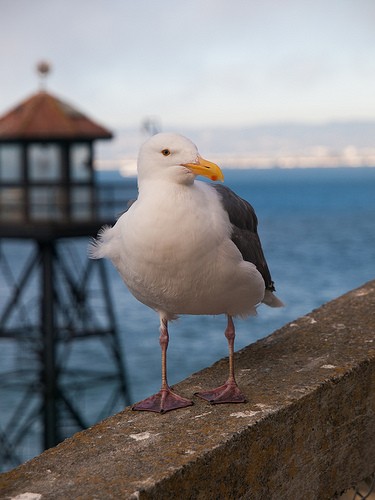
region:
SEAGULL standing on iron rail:
[84, 128, 280, 413]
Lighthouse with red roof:
[0, 54, 115, 234]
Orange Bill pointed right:
[177, 151, 226, 182]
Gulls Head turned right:
[127, 126, 221, 187]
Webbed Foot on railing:
[125, 379, 191, 411]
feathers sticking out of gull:
[83, 222, 120, 259]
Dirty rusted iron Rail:
[1, 410, 355, 489]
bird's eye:
[155, 144, 173, 159]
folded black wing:
[207, 180, 283, 305]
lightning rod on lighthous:
[27, 54, 57, 92]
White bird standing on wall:
[96, 121, 285, 430]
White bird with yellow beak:
[107, 113, 267, 404]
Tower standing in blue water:
[1, 47, 132, 447]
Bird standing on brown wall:
[42, 119, 372, 494]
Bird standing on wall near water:
[50, 111, 372, 484]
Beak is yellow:
[184, 158, 224, 185]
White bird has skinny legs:
[101, 121, 261, 408]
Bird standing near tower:
[4, 44, 279, 406]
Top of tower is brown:
[2, 55, 118, 146]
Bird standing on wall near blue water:
[87, 138, 373, 406]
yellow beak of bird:
[186, 157, 229, 190]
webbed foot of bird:
[124, 375, 185, 417]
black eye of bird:
[160, 146, 171, 158]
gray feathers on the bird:
[212, 183, 282, 308]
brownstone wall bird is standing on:
[103, 421, 329, 470]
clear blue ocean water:
[272, 180, 337, 280]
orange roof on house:
[1, 93, 112, 136]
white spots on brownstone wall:
[125, 422, 181, 449]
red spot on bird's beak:
[210, 172, 220, 180]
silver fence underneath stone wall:
[342, 477, 374, 498]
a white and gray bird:
[57, 100, 310, 400]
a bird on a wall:
[51, 115, 316, 469]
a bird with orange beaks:
[85, 112, 331, 462]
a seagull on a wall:
[54, 114, 327, 498]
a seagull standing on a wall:
[84, 123, 341, 496]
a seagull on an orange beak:
[88, 106, 293, 403]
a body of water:
[252, 171, 335, 245]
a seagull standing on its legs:
[57, 107, 345, 450]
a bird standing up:
[45, 106, 300, 432]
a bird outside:
[69, 120, 307, 498]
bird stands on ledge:
[106, 139, 297, 415]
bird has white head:
[139, 110, 200, 197]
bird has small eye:
[163, 143, 172, 162]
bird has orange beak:
[183, 162, 227, 188]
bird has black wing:
[214, 186, 274, 293]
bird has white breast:
[134, 217, 226, 311]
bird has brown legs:
[152, 318, 250, 396]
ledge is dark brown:
[100, 325, 337, 456]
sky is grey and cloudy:
[102, 6, 245, 101]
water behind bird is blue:
[257, 168, 313, 289]